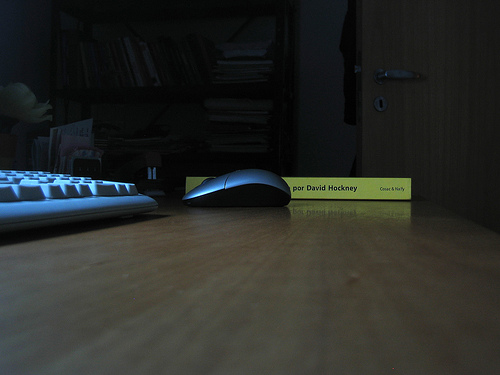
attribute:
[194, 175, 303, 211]
mouse — lower part, silver, wireless, black, gray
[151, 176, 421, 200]
book — yellow, side, bottom, directory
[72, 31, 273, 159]
books — stacked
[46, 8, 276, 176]
shelf — part, black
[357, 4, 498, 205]
door — part, office, wooden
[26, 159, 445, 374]
desk — wooden, wood, brown, laminated, wood pattern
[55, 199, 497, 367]
table — brown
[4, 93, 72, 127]
flower — white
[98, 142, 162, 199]
stapler — brown, large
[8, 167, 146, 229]
keyboard — blue, white, sideview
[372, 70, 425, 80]
handle — silver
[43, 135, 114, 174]
papers — assortment